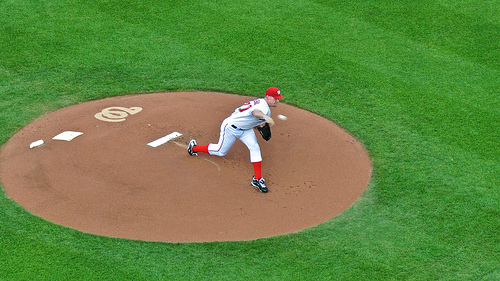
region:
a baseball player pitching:
[100, 25, 339, 182]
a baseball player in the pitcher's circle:
[133, 16, 410, 274]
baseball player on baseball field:
[117, 5, 412, 272]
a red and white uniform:
[171, 40, 333, 204]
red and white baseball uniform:
[123, 52, 385, 209]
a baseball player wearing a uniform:
[164, 57, 373, 212]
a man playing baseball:
[151, 37, 373, 234]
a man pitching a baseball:
[175, 34, 345, 206]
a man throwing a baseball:
[100, 81, 413, 245]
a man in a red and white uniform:
[157, 27, 349, 156]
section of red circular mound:
[107, 210, 203, 249]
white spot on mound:
[188, 152, 233, 182]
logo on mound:
[76, 95, 157, 145]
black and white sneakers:
[174, 133, 208, 168]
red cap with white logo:
[262, 72, 294, 105]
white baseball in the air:
[276, 109, 306, 139]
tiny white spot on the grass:
[440, 140, 466, 165]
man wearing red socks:
[238, 153, 269, 175]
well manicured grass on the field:
[219, 27, 342, 55]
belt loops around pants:
[207, 115, 254, 137]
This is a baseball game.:
[5, 7, 491, 270]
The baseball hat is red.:
[262, 82, 285, 102]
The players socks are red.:
[252, 160, 264, 180]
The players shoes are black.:
[250, 176, 271, 197]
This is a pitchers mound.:
[66, 92, 334, 227]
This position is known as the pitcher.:
[190, 70, 320, 202]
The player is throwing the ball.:
[192, 67, 304, 200]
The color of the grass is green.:
[63, 17, 270, 71]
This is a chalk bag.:
[20, 134, 50, 153]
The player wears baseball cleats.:
[181, 135, 277, 203]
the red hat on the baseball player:
[266, 85, 283, 99]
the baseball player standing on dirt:
[184, 86, 285, 191]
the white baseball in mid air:
[277, 113, 286, 120]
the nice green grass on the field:
[372, 11, 489, 191]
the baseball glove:
[258, 122, 272, 140]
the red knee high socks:
[191, 142, 264, 179]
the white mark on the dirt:
[149, 128, 179, 148]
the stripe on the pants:
[210, 121, 229, 158]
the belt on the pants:
[222, 115, 254, 132]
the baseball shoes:
[185, 135, 267, 197]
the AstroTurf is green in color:
[376, 70, 469, 152]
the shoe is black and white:
[244, 172, 277, 202]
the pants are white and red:
[218, 117, 265, 169]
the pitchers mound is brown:
[138, 185, 214, 229]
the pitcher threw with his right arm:
[250, 102, 293, 134]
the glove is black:
[253, 119, 283, 146]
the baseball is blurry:
[273, 110, 298, 125]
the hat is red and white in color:
[260, 82, 290, 107]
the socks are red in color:
[238, 154, 278, 182]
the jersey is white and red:
[226, 95, 276, 137]